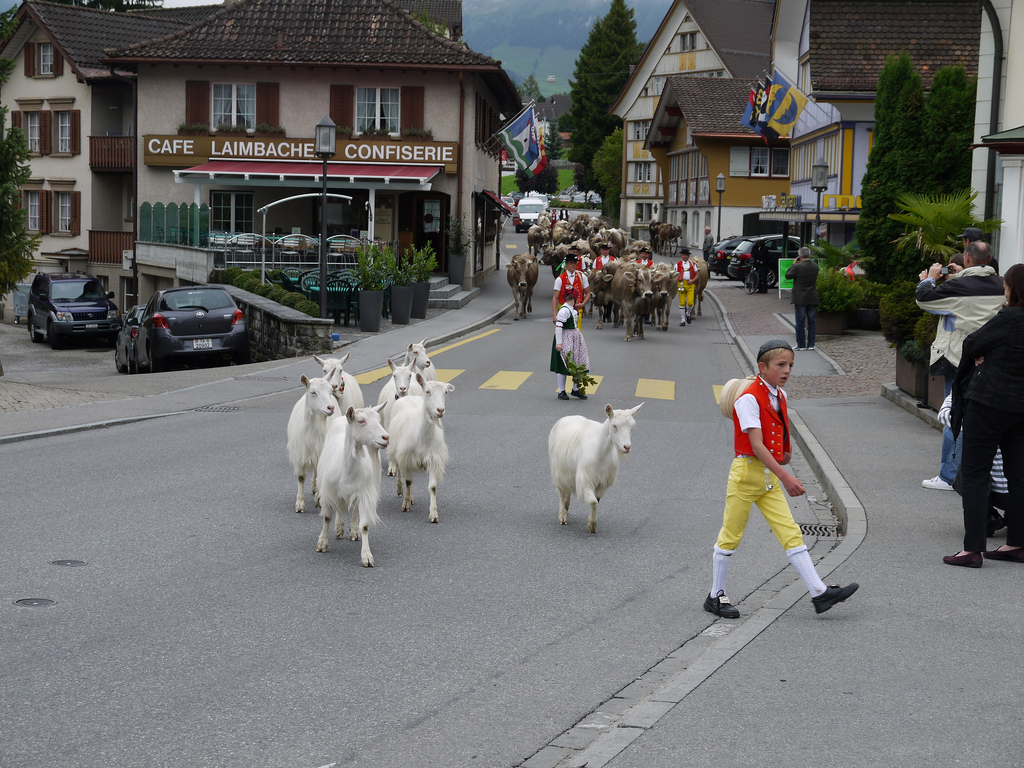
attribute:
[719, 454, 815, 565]
pants — yellow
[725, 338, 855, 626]
outfit — yellow, orange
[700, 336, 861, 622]
boy — brown haired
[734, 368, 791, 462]
vest — red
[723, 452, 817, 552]
pants — yellow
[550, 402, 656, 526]
goat — white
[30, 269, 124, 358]
suv — black, parked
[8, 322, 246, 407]
road — brick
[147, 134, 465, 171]
sign — brown, rectangle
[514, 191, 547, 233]
van — white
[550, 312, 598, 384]
dress — green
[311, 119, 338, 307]
light pole — black, clear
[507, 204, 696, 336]
cattle — brown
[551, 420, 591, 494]
fur — white